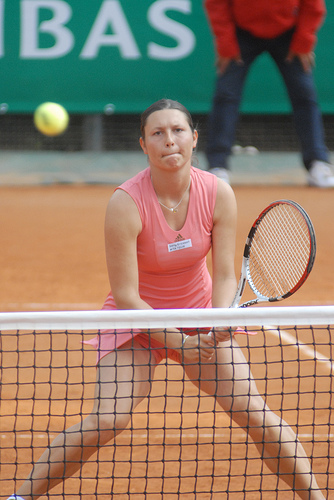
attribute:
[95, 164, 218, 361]
clothing — pink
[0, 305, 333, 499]
net — black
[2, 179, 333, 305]
court — dirt, clay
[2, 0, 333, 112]
banner — green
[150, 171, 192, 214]
necklace — metal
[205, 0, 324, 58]
sweater — red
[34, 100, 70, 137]
ball — green, flying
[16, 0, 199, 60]
letters — bas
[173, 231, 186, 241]
symbol — adidas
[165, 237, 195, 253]
nametag — white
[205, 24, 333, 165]
jeans — blue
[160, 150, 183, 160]
lips — pursed